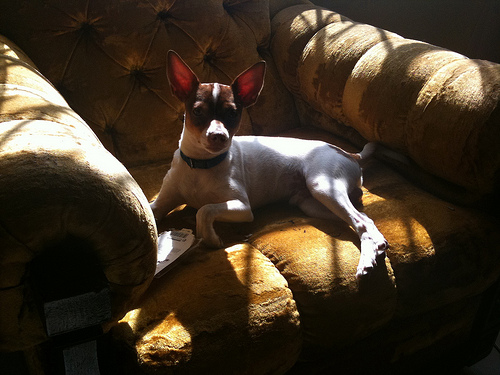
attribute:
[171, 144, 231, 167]
collar — blue 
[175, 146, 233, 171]
collar — black